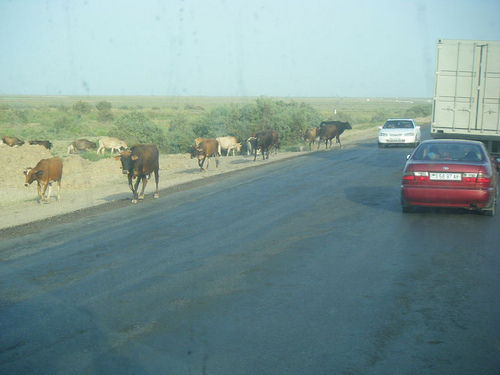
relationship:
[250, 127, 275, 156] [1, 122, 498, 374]
cow on side of road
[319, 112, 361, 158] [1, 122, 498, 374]
cow on side of road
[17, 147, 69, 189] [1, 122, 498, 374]
cow on side of road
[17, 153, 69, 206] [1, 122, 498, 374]
cow on side of road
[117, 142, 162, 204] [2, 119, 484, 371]
cow on street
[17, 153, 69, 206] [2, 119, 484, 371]
cow on street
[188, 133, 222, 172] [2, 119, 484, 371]
cow on street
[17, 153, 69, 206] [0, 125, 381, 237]
cow on dirt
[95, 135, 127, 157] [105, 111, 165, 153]
cow grazing next to bush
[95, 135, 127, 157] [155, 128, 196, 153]
cow grazing next to bush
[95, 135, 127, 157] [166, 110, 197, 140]
cow grazing next to bush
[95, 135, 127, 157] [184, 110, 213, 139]
cow grazing next to bush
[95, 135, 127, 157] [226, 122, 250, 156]
cow grazing next to bush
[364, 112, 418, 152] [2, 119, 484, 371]
car driving on street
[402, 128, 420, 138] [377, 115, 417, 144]
headlight mounted on car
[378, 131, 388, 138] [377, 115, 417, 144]
headlight mounted on car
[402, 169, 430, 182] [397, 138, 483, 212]
taillight mounted on car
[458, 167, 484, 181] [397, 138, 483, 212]
taillight mounted on car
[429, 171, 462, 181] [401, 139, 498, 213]
license plate mounted on car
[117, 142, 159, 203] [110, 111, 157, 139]
cow standing close to bush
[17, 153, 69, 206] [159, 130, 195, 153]
cow standing close to bush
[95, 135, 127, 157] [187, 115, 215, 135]
cow standing close to bush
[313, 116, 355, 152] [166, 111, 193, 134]
cow standing close to bush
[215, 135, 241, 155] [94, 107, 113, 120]
cow standing close to bush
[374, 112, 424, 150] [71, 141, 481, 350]
car driving on road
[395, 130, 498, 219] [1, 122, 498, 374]
car driving on road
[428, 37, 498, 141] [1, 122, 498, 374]
trailer driving on road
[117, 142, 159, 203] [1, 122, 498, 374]
cow walking on road